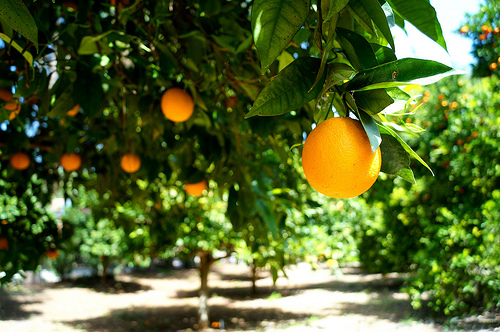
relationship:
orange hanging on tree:
[120, 153, 139, 171] [1, 0, 455, 246]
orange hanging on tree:
[160, 87, 193, 122] [1, 2, 452, 330]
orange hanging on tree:
[160, 87, 193, 122] [196, 246, 208, 325]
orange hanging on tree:
[301, 120, 382, 198] [196, 246, 208, 325]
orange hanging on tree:
[58, 153, 80, 170] [196, 246, 208, 325]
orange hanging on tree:
[120, 153, 139, 171] [196, 246, 208, 325]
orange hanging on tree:
[301, 116, 382, 198] [196, 246, 208, 325]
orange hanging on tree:
[46, 246, 58, 258] [2, 166, 76, 284]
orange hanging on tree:
[457, 24, 471, 39] [440, 1, 498, 76]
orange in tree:
[160, 87, 193, 122] [383, 80, 497, 312]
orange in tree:
[111, 152, 153, 176] [93, 34, 289, 322]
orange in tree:
[301, 116, 382, 198] [1, 2, 452, 330]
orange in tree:
[301, 116, 382, 198] [1, 0, 455, 246]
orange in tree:
[301, 116, 382, 198] [3, 0, 498, 329]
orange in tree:
[457, 24, 471, 36] [3, 0, 498, 329]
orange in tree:
[160, 87, 193, 122] [3, 0, 498, 329]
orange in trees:
[301, 116, 382, 198] [1, 0, 451, 286]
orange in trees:
[160, 87, 193, 122] [94, 183, 239, 311]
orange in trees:
[301, 116, 382, 198] [228, 180, 290, 301]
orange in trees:
[120, 153, 139, 171] [453, 3, 498, 60]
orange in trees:
[160, 87, 193, 122] [453, 3, 498, 60]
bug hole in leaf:
[385, 67, 399, 80] [337, 55, 470, 95]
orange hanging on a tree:
[163, 77, 197, 126] [65, 63, 290, 305]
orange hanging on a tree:
[2, 237, 9, 249] [0, 0, 452, 277]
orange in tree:
[301, 116, 382, 198] [290, 111, 380, 198]